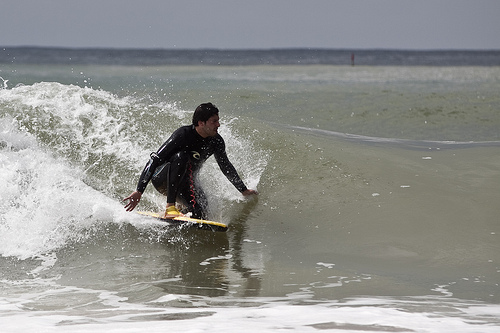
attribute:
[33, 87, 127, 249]
sea foam — white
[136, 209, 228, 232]
surfboard — yellow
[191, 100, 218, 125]
hair — black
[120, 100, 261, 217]
man — kneeling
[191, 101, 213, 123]
hair — black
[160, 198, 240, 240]
surfboard — yellow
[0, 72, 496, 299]
wave — swelling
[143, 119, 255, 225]
wetsuit — black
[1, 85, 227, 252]
water — splashed